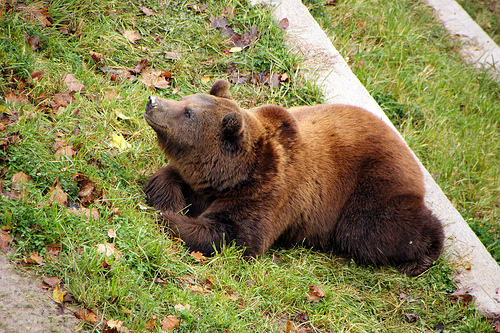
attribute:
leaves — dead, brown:
[2, 7, 294, 236]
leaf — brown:
[39, 176, 69, 209]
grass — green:
[9, 25, 497, 325]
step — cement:
[249, 1, 498, 331]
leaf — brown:
[70, 162, 110, 218]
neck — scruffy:
[219, 96, 304, 200]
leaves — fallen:
[113, 65, 173, 85]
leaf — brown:
[189, 248, 206, 265]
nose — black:
[141, 90, 159, 110]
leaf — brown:
[65, 62, 87, 96]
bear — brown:
[143, 77, 447, 279]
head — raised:
[146, 78, 255, 188]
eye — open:
[178, 98, 203, 125]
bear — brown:
[145, 86, 493, 261]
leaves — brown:
[67, 157, 117, 242]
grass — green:
[0, 1, 498, 331]